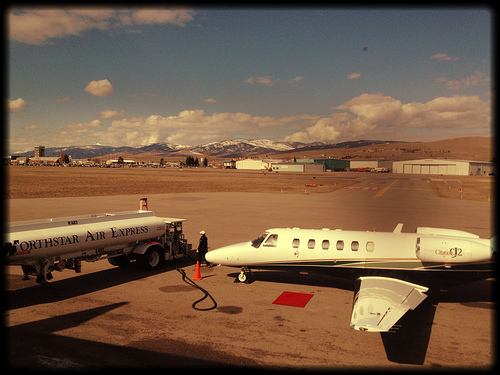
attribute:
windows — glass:
[291, 237, 376, 256]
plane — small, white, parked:
[204, 222, 493, 336]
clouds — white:
[11, 7, 196, 46]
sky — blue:
[9, 8, 492, 145]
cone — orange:
[189, 261, 203, 281]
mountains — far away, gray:
[15, 136, 405, 158]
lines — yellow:
[351, 174, 432, 202]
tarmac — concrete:
[8, 174, 491, 369]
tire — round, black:
[138, 244, 165, 273]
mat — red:
[272, 289, 315, 308]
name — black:
[5, 220, 150, 254]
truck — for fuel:
[9, 209, 192, 286]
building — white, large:
[393, 157, 492, 177]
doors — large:
[403, 163, 457, 176]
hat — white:
[199, 228, 206, 236]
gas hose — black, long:
[167, 247, 218, 315]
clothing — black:
[197, 235, 210, 265]